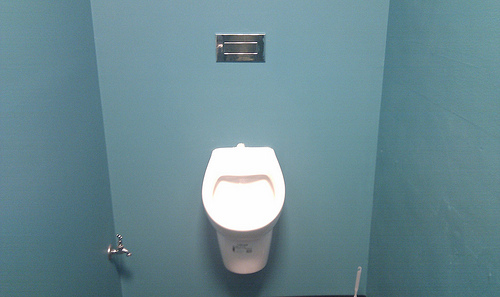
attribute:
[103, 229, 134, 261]
faucet — silver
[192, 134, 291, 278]
urinal — white, porcelain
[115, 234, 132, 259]
spigot — metal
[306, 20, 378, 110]
wall — teal, blue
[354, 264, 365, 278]
handle — white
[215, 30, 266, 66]
box — silver, metal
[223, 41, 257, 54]
shape — rectangle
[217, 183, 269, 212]
bowl — white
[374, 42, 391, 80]
corner — blue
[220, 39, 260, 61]
square — stainless, steel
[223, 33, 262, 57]
mount — silver